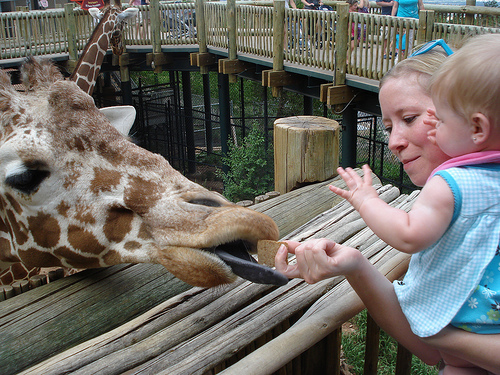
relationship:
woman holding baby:
[273, 45, 495, 374] [335, 36, 499, 330]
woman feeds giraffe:
[273, 45, 495, 374] [1, 63, 287, 287]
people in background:
[280, 2, 418, 56] [2, 2, 500, 177]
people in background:
[78, 1, 196, 37] [2, 2, 500, 177]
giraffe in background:
[73, 6, 137, 98] [2, 2, 500, 177]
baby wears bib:
[335, 36, 499, 330] [432, 150, 500, 168]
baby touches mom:
[335, 36, 499, 330] [273, 45, 495, 374]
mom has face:
[273, 45, 495, 374] [380, 81, 449, 187]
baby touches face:
[335, 36, 499, 330] [380, 81, 449, 187]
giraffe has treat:
[1, 63, 287, 287] [259, 238, 286, 266]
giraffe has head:
[73, 6, 137, 98] [91, 9, 137, 54]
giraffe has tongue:
[1, 63, 287, 287] [216, 249, 287, 285]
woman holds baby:
[273, 45, 495, 374] [335, 36, 499, 330]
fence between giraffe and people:
[0, 120, 419, 373] [2, 41, 499, 369]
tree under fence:
[218, 127, 266, 197] [0, 3, 428, 91]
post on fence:
[275, 113, 341, 189] [0, 120, 419, 373]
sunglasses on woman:
[408, 39, 452, 56] [273, 45, 495, 374]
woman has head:
[273, 45, 495, 374] [379, 50, 450, 190]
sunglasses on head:
[408, 39, 452, 56] [379, 50, 450, 190]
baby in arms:
[335, 36, 499, 330] [278, 245, 499, 370]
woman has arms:
[273, 45, 495, 374] [278, 245, 499, 370]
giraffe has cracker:
[1, 63, 287, 287] [259, 238, 286, 266]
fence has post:
[0, 3, 428, 91] [338, 5, 350, 84]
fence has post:
[0, 3, 428, 91] [272, 2, 285, 75]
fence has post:
[0, 3, 428, 91] [227, 2, 237, 61]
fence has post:
[0, 3, 428, 91] [196, 2, 204, 54]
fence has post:
[0, 3, 428, 91] [151, 3, 162, 50]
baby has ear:
[335, 36, 499, 330] [471, 115, 488, 144]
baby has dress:
[335, 36, 499, 330] [397, 169, 500, 337]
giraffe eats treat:
[1, 63, 287, 287] [259, 238, 286, 266]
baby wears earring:
[335, 36, 499, 330] [472, 136, 477, 142]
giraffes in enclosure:
[6, 6, 285, 289] [4, 55, 390, 272]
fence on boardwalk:
[0, 3, 428, 91] [3, 4, 500, 90]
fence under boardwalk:
[113, 86, 404, 186] [3, 4, 500, 90]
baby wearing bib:
[335, 36, 499, 330] [432, 150, 500, 168]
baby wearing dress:
[335, 36, 499, 330] [397, 169, 500, 337]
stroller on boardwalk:
[279, 10, 313, 56] [3, 4, 500, 90]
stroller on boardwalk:
[314, 9, 343, 49] [3, 4, 500, 90]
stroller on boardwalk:
[160, 5, 198, 39] [3, 4, 500, 90]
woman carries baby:
[273, 45, 495, 374] [335, 36, 499, 330]